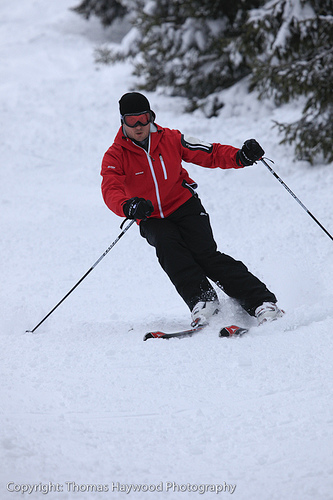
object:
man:
[102, 92, 279, 328]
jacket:
[102, 129, 241, 222]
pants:
[138, 190, 277, 317]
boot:
[190, 295, 218, 329]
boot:
[252, 296, 283, 325]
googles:
[121, 110, 154, 130]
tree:
[244, 0, 333, 165]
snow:
[74, 1, 332, 167]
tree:
[73, 0, 275, 109]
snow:
[0, 0, 333, 500]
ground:
[0, 1, 331, 499]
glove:
[121, 194, 155, 219]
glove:
[237, 138, 265, 169]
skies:
[143, 324, 208, 343]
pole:
[262, 156, 333, 241]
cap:
[119, 92, 151, 116]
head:
[120, 94, 154, 143]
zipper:
[144, 149, 165, 224]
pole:
[27, 216, 137, 338]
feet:
[252, 301, 280, 324]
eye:
[127, 116, 134, 125]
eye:
[140, 115, 146, 124]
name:
[3, 479, 239, 499]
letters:
[229, 484, 237, 493]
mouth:
[131, 129, 145, 139]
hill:
[1, 0, 332, 498]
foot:
[191, 297, 221, 330]